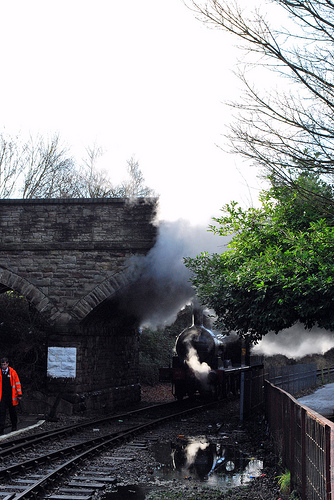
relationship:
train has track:
[156, 268, 280, 410] [30, 375, 188, 452]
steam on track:
[257, 280, 318, 370] [30, 375, 188, 452]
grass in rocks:
[272, 453, 309, 489] [251, 454, 301, 495]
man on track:
[2, 351, 24, 416] [30, 375, 188, 452]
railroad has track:
[54, 363, 215, 470] [30, 375, 188, 452]